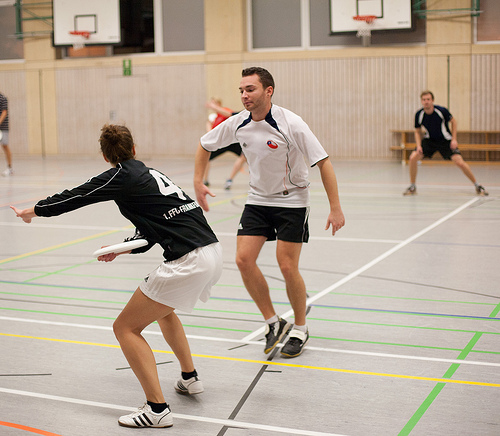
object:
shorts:
[137, 241, 224, 312]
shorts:
[1, 132, 11, 147]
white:
[186, 282, 199, 292]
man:
[193, 67, 344, 358]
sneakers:
[117, 377, 204, 428]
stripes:
[133, 413, 152, 428]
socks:
[147, 370, 197, 412]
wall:
[0, 0, 498, 158]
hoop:
[69, 30, 91, 50]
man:
[403, 92, 488, 197]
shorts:
[235, 205, 309, 243]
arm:
[11, 175, 116, 225]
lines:
[303, 191, 490, 314]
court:
[0, 152, 494, 435]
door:
[52, 62, 206, 157]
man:
[10, 125, 220, 427]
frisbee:
[94, 239, 148, 258]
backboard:
[55, 1, 122, 45]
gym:
[3, 1, 497, 427]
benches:
[391, 128, 497, 162]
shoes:
[265, 319, 309, 354]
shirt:
[197, 105, 330, 210]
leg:
[109, 288, 176, 403]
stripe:
[433, 107, 452, 142]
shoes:
[402, 183, 489, 196]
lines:
[317, 319, 497, 339]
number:
[149, 169, 188, 200]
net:
[357, 21, 375, 40]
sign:
[123, 60, 133, 77]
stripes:
[291, 330, 307, 342]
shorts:
[417, 139, 461, 159]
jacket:
[35, 159, 218, 260]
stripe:
[400, 353, 465, 434]